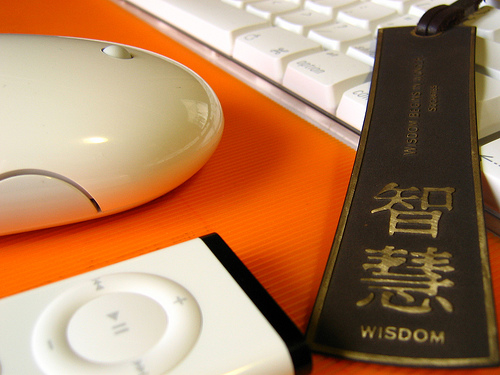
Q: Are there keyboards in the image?
A: Yes, there is a keyboard.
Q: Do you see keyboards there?
A: Yes, there is a keyboard.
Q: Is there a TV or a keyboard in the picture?
A: Yes, there is a keyboard.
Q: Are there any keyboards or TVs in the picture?
A: Yes, there is a keyboard.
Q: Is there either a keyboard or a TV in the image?
A: Yes, there is a keyboard.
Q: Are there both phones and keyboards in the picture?
A: No, there is a keyboard but no phones.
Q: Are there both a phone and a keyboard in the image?
A: No, there is a keyboard but no phones.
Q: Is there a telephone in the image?
A: No, there are no phones.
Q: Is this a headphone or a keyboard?
A: This is a keyboard.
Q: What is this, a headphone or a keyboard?
A: This is a keyboard.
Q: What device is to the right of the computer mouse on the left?
A: The device is a keyboard.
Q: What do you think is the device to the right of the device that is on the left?
A: The device is a keyboard.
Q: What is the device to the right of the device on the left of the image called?
A: The device is a keyboard.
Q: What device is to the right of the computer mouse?
A: The device is a keyboard.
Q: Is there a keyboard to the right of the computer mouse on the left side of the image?
A: Yes, there is a keyboard to the right of the mouse.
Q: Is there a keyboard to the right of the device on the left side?
A: Yes, there is a keyboard to the right of the mouse.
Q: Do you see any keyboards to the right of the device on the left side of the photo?
A: Yes, there is a keyboard to the right of the mouse.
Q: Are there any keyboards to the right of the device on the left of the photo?
A: Yes, there is a keyboard to the right of the mouse.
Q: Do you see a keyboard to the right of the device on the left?
A: Yes, there is a keyboard to the right of the mouse.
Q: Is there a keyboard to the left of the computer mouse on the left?
A: No, the keyboard is to the right of the computer mouse.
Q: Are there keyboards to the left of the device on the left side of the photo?
A: No, the keyboard is to the right of the computer mouse.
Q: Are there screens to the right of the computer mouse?
A: No, there is a keyboard to the right of the computer mouse.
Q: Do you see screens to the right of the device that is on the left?
A: No, there is a keyboard to the right of the computer mouse.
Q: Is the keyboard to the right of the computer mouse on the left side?
A: Yes, the keyboard is to the right of the mouse.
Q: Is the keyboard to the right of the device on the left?
A: Yes, the keyboard is to the right of the mouse.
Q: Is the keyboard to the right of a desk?
A: No, the keyboard is to the right of the mouse.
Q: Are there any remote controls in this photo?
A: Yes, there is a remote control.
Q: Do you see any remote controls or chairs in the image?
A: Yes, there is a remote control.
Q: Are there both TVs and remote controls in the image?
A: No, there is a remote control but no televisions.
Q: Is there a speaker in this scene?
A: No, there are no speakers.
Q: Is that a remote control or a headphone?
A: That is a remote control.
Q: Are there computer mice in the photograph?
A: Yes, there is a computer mouse.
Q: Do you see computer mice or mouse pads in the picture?
A: Yes, there is a computer mouse.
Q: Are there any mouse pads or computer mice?
A: Yes, there is a computer mouse.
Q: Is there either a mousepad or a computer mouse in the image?
A: Yes, there is a computer mouse.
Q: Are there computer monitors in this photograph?
A: No, there are no computer monitors.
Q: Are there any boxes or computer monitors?
A: No, there are no computer monitors or boxes.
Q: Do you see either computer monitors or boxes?
A: No, there are no computer monitors or boxes.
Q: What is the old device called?
A: The device is a computer mouse.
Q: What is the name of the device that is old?
A: The device is a computer mouse.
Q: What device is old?
A: The device is a computer mouse.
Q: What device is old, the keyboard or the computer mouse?
A: The computer mouse is old.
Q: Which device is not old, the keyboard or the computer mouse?
A: The keyboard is not old.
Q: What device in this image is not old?
A: The device is a keyboard.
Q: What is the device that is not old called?
A: The device is a keyboard.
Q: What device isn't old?
A: The device is a keyboard.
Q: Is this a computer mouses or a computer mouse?
A: This is a computer mouse.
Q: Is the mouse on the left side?
A: Yes, the mouse is on the left of the image.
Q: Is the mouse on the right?
A: No, the mouse is on the left of the image.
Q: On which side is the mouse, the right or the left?
A: The mouse is on the left of the image.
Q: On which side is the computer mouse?
A: The computer mouse is on the left of the image.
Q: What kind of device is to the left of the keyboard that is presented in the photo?
A: The device is a computer mouse.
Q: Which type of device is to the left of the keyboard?
A: The device is a computer mouse.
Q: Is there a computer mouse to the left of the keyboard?
A: Yes, there is a computer mouse to the left of the keyboard.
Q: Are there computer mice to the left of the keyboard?
A: Yes, there is a computer mouse to the left of the keyboard.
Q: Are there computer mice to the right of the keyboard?
A: No, the computer mouse is to the left of the keyboard.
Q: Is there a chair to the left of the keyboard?
A: No, there is a computer mouse to the left of the keyboard.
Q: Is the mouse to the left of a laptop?
A: No, the mouse is to the left of the keyboard.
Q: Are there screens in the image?
A: No, there are no screens.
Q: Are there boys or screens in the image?
A: No, there are no screens or boys.